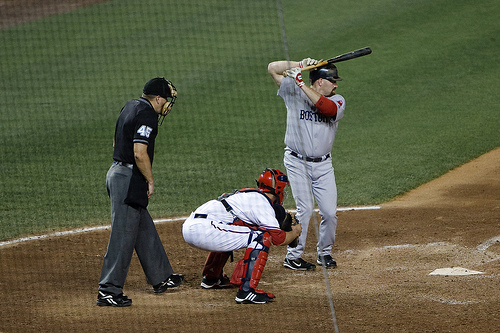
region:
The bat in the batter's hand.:
[282, 48, 384, 78]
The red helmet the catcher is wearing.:
[254, 168, 288, 193]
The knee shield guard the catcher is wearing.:
[256, 232, 281, 295]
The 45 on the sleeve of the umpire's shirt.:
[131, 116, 156, 138]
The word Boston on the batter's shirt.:
[295, 108, 335, 130]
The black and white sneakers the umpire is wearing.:
[90, 273, 180, 303]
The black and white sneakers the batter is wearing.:
[282, 251, 332, 278]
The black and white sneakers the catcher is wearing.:
[200, 273, 280, 318]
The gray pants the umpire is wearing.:
[103, 168, 167, 295]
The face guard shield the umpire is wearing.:
[161, 78, 177, 125]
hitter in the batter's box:
[270, 40, 370, 275]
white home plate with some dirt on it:
[430, 262, 482, 276]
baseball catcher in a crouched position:
[184, 167, 298, 306]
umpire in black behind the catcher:
[99, 80, 186, 305]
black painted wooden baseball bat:
[291, 47, 371, 71]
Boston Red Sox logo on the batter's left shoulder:
[337, 99, 345, 109]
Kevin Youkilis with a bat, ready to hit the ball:
[273, 41, 368, 277]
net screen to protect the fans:
[2, 2, 338, 332]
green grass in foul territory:
[7, 0, 491, 241]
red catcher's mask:
[261, 167, 290, 204]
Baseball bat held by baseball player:
[292, 46, 373, 77]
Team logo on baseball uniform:
[299, 106, 326, 123]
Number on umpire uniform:
[136, 125, 153, 136]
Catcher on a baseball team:
[182, 167, 303, 307]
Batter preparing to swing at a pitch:
[264, 45, 376, 275]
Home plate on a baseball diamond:
[430, 267, 485, 274]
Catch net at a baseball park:
[0, 0, 339, 331]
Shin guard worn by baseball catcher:
[249, 248, 276, 300]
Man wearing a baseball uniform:
[266, 45, 346, 273]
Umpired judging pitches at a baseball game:
[97, 76, 187, 305]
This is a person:
[93, 63, 190, 310]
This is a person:
[176, 145, 300, 311]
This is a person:
[271, 37, 358, 282]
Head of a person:
[124, 70, 187, 125]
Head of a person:
[249, 150, 298, 220]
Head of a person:
[301, 43, 345, 110]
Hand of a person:
[131, 115, 158, 205]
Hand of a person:
[261, 203, 313, 253]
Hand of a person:
[252, 41, 316, 96]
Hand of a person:
[286, 60, 340, 126]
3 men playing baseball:
[94, 15, 389, 292]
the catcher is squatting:
[172, 155, 317, 322]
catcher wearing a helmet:
[245, 143, 288, 197]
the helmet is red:
[238, 163, 300, 203]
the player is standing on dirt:
[257, 15, 380, 288]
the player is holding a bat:
[247, 42, 392, 153]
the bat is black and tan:
[280, 37, 388, 87]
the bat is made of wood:
[275, 40, 382, 85]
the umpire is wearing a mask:
[132, 50, 196, 130]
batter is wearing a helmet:
[292, 47, 351, 90]